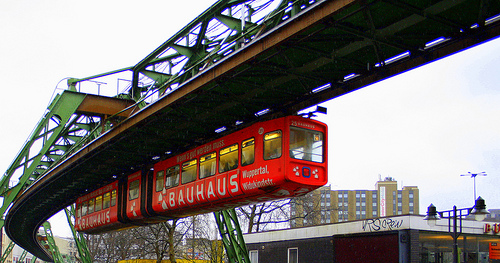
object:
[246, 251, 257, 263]
window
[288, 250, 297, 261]
window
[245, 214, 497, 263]
building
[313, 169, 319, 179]
light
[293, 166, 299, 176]
light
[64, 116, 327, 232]
train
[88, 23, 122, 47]
sky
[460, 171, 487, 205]
antenna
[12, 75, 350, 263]
railcar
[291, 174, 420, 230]
building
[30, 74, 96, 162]
scaffolding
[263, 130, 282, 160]
window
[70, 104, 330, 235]
car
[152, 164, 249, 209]
paint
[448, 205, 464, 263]
pole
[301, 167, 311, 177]
sign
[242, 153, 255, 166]
passenger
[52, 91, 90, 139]
metal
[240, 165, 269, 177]
letter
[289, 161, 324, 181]
square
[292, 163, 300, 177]
symbol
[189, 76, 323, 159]
track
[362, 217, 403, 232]
graffiti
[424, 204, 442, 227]
lamp